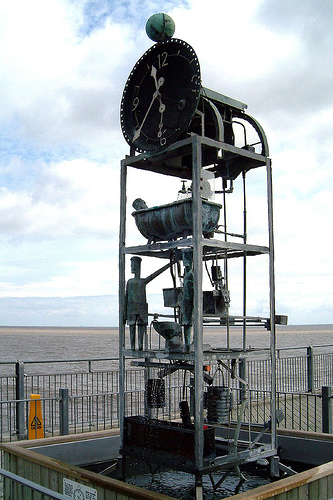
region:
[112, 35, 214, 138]
Clock is in tower.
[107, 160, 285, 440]
Tower is grey color.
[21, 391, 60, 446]
Board is yellow and black color.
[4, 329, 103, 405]
Water is behind the fence.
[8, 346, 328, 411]
Fence is grey color.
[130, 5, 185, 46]
Globe is in top of the tower.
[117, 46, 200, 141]
11.38 is the time shown.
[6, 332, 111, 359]
water is blue color.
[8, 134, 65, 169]
Sky is blue color.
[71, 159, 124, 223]
Clouds are white color.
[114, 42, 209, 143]
clock in the photo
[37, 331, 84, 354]
water next to land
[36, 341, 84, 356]
ripples in the water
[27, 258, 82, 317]
hill and sky in the background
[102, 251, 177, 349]
humanoid figure in photo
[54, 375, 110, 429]
fence next to object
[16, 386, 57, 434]
yellow item next to fence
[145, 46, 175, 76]
the number twelve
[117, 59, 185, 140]
hands of the clock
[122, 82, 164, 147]
long hand of clock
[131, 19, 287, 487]
A clock tower near the sea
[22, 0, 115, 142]
A blue color sky with clouds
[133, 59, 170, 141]
White color needles in the clock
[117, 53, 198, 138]
Numeric letters of the clock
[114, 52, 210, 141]
Black and white color of the clock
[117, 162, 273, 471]
A metal stand with clock near the sea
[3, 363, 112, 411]
Steel fencing near the sea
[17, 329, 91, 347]
Sea water near the clock tower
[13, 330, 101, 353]
Small waves in the sea water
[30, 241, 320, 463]
A blue sky with sea water and clock tower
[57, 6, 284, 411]
this is an electrical tower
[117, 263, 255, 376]
this tower is made of metal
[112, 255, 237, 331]
this is art work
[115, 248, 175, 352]
this metal is shaped like a man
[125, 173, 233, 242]
this is a man in a bath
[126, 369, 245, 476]
there is water splashing here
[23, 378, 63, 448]
this is a caution sign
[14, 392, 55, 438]
the sign is yellow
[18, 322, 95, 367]
this is the ocean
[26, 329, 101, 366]
the water is dark blue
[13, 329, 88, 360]
Water is blue color.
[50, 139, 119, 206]
Clouds are white color.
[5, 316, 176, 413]
Water is behind the fence.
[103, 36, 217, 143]
Clock is in top of the tower.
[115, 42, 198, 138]
11.38 is time shown.